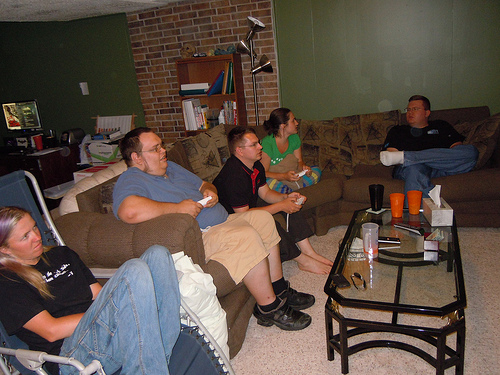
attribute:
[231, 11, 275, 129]
lamp — silver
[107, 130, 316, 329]
man — large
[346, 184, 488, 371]
table — black, framed, coffee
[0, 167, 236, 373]
chair — white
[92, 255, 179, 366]
jeans — blue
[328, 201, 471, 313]
surface — glass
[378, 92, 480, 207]
person — sitting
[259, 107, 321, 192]
person — sitting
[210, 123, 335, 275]
person — sitting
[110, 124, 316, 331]
person — sitting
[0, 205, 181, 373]
person — sitting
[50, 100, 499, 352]
sofa — brown, sectional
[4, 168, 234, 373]
fabric —  blue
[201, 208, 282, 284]
shorts — tan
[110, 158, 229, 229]
shirt — blue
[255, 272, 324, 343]
feet — man's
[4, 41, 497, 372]
room — full